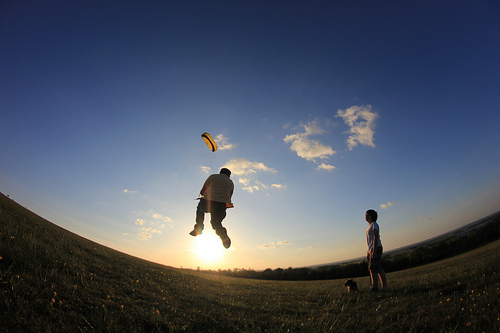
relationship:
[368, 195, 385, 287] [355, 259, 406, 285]
woman wearing capris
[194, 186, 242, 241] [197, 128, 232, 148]
man flying kite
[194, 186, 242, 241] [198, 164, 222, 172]
man holding onto harness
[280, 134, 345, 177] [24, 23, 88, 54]
clouds in sky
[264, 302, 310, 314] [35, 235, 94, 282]
grass in field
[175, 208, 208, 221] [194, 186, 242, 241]
leg of man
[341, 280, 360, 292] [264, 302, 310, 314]
dog in grass